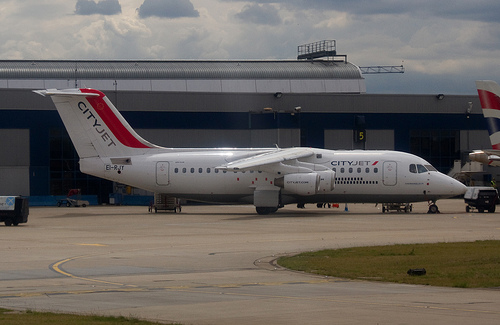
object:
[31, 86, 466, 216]
plane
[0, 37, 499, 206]
airport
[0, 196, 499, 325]
tarmac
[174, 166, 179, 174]
windows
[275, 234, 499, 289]
grass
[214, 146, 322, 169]
wing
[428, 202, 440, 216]
wheels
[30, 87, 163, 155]
tail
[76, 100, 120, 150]
writing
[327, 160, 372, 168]
logo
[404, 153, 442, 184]
cockpit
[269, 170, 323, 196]
engines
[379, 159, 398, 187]
door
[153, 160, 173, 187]
door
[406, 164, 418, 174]
windows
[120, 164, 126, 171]
numbers